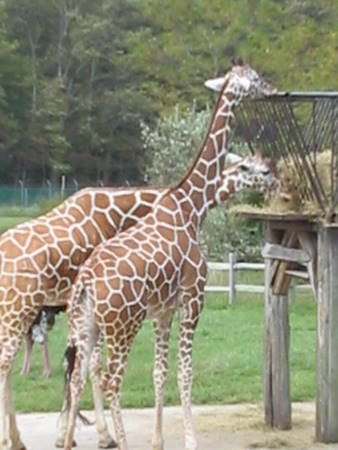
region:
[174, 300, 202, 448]
a long giraffe leg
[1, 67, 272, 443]
two tall giraffes eating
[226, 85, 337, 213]
a feeding mechanism for giraffes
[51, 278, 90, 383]
a long bushy tail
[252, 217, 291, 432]
a long pillar of wood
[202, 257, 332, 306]
a short wooden fence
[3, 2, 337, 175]
a lush green forest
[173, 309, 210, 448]
a white and brown giraffe leg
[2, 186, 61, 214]
a green fence in the distance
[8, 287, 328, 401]
a patch of green grass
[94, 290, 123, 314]
Brown spots on an animal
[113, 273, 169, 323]
Brown spots on an animal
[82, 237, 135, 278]
Brown spots on an animal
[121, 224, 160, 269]
Brown spots on an animal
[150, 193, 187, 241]
Brown spots on an animal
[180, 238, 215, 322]
Brown spots on an animal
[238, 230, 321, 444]
Long wooden beam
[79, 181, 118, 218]
Brown spots on an animal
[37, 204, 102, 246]
Brown spots on an animal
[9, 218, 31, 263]
Brown spots on an animal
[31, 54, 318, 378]
two giraffes are eating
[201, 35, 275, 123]
giraffe has white ears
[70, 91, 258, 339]
brown and white spots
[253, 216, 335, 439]
brown and wooden legs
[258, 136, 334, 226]
gold hay in bin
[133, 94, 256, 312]
green tree behind giraffes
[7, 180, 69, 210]
green fence in background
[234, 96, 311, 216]
brown bars on bin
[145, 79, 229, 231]
giraffe has brown mane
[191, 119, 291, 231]
the giraffe is eating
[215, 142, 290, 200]
the giraffe is eating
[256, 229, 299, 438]
the wood is gray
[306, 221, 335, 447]
the wood is gray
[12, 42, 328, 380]
giraffes standing together outside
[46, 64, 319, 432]
two giraffes standing outside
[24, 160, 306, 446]
two giraffes standing together outside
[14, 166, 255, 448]
two giraffes standing in a field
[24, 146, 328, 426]
giraffes in a fenced in area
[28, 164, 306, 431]
fenced in giraffes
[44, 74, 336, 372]
giraffes eating out of the basket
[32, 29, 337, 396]
two giraffes that are eating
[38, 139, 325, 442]
giraffes that are eating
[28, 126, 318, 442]
giraffes behind fences